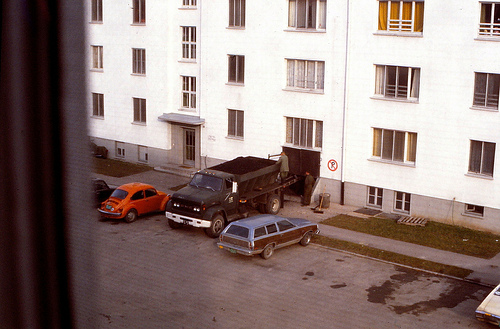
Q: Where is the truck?
A: On the curb.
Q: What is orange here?
A: A car.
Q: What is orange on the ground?
A: A volkswagen.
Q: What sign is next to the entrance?
A: No parking sign.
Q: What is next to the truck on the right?
A: A station wagon.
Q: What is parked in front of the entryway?
A: A big truck.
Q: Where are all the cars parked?
A: In a parking lot.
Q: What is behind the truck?
A: A building.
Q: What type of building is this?
A: An apartment building.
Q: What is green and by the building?
A: Grass.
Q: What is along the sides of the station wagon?
A: Wood.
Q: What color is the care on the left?
A: Orange.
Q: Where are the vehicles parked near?
A: A building.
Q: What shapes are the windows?
A: Rectangles.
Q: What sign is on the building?
A: No Parking.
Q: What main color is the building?
A: White.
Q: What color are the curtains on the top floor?
A: Yellow.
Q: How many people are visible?
A: One.